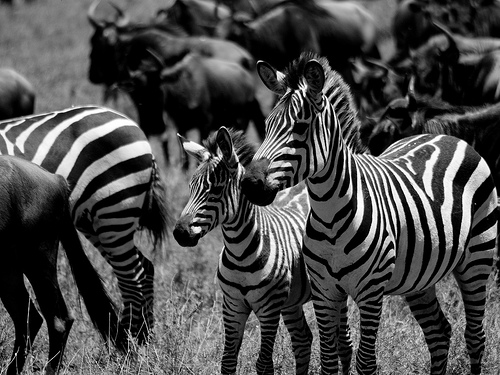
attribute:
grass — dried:
[0, 0, 497, 372]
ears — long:
[173, 125, 243, 160]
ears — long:
[252, 52, 333, 96]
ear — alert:
[305, 63, 322, 98]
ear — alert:
[256, 60, 286, 88]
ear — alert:
[217, 125, 241, 165]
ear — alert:
[178, 137, 209, 157]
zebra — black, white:
[238, 52, 495, 373]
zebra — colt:
[167, 125, 350, 374]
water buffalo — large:
[81, 1, 264, 145]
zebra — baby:
[174, 99, 478, 297]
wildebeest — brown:
[78, 0, 262, 93]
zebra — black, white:
[174, 63, 468, 345]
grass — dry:
[4, 171, 499, 372]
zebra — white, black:
[0, 110, 166, 340]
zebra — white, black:
[174, 123, 311, 373]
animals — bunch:
[3, 1, 498, 372]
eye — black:
[290, 120, 308, 135]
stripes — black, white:
[1, 100, 168, 345]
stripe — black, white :
[342, 161, 372, 254]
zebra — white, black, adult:
[239, 70, 499, 364]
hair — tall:
[283, 49, 365, 155]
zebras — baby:
[153, 37, 494, 372]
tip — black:
[173, 225, 186, 238]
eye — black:
[286, 110, 317, 141]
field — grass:
[2, 1, 496, 371]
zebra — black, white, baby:
[169, 115, 329, 373]